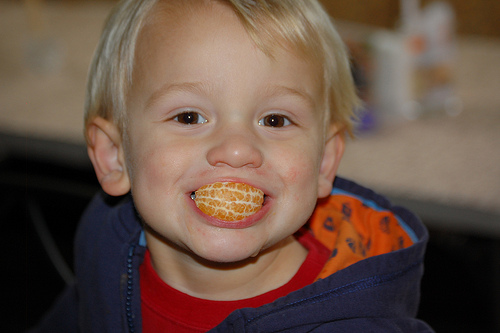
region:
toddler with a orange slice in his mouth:
[66, 11, 412, 331]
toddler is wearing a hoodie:
[70, 13, 440, 329]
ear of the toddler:
[79, 102, 130, 209]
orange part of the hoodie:
[322, 207, 370, 255]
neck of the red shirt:
[142, 272, 221, 329]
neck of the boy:
[180, 272, 257, 293]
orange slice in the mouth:
[192, 181, 262, 224]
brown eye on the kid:
[156, 100, 211, 135]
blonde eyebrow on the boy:
[256, 75, 327, 103]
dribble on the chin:
[235, 243, 274, 265]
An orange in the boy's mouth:
[192, 183, 264, 220]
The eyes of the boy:
[168, 108, 290, 127]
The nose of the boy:
[208, 123, 263, 165]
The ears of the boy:
[79, 117, 341, 197]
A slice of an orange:
[193, 185, 265, 215]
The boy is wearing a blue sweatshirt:
[35, 175, 430, 331]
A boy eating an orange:
[34, 1, 431, 331]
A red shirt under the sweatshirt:
[137, 233, 329, 332]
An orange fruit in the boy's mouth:
[193, 184, 263, 221]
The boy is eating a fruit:
[45, 1, 433, 330]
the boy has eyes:
[149, 102, 321, 139]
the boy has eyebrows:
[135, 59, 319, 109]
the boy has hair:
[272, 20, 334, 47]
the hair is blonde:
[87, 50, 119, 91]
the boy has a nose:
[200, 138, 268, 171]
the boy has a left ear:
[72, 100, 130, 205]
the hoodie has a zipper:
[115, 255, 142, 326]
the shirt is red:
[147, 282, 213, 330]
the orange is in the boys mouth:
[167, 170, 282, 227]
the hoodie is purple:
[297, 272, 414, 327]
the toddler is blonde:
[38, 0, 438, 328]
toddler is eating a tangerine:
[65, 0, 390, 295]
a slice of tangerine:
[193, 175, 265, 226]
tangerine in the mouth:
[183, 174, 277, 229]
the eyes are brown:
[156, 96, 306, 138]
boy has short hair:
[30, 0, 421, 305]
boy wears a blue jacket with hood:
[5, 3, 445, 325]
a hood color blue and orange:
[293, 180, 440, 327]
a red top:
[128, 240, 327, 329]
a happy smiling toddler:
[56, 2, 393, 319]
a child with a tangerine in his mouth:
[67, 0, 347, 260]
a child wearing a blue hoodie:
[65, 52, 439, 329]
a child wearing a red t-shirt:
[72, 55, 367, 325]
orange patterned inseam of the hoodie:
[328, 203, 398, 268]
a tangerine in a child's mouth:
[186, 173, 266, 228]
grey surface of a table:
[415, 139, 475, 199]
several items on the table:
[337, 10, 479, 145]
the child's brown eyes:
[153, 97, 298, 140]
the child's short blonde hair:
[73, 0, 353, 100]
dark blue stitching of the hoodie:
[329, 275, 381, 301]